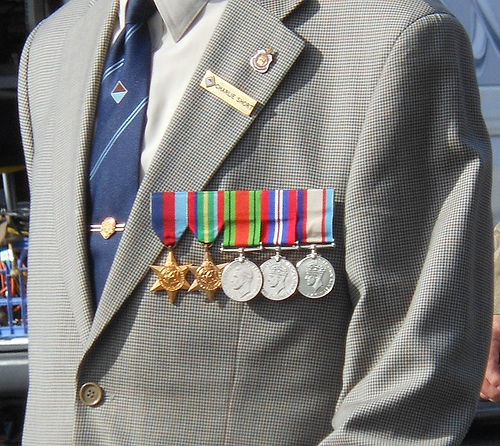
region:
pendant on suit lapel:
[249, 42, 273, 71]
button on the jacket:
[78, 372, 104, 410]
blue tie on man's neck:
[76, 2, 149, 305]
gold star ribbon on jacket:
[149, 190, 189, 297]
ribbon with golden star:
[192, 190, 225, 299]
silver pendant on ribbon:
[223, 189, 261, 301]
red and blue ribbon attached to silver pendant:
[262, 182, 294, 303]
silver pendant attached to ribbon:
[299, 188, 333, 300]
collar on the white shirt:
[156, 0, 212, 42]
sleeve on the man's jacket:
[336, 16, 497, 444]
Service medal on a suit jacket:
[139, 172, 337, 319]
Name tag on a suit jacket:
[181, 63, 268, 131]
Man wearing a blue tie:
[83, 0, 145, 340]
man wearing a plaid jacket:
[281, 26, 451, 165]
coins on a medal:
[215, 249, 351, 302]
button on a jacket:
[75, 379, 104, 407]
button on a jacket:
[248, 41, 274, 75]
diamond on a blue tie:
[102, 77, 141, 109]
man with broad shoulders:
[326, 4, 486, 102]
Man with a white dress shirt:
[156, 38, 194, 91]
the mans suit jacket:
[16, 1, 493, 443]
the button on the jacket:
[80, 381, 102, 405]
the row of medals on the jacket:
[149, 189, 334, 301]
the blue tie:
[82, 0, 153, 316]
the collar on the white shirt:
[116, 0, 209, 44]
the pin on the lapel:
[249, 45, 274, 72]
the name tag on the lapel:
[200, 69, 256, 114]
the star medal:
[150, 250, 196, 303]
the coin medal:
[221, 258, 262, 300]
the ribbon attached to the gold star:
[149, 192, 188, 246]